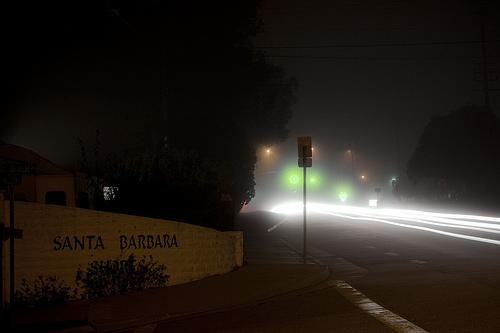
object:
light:
[281, 199, 498, 245]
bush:
[68, 249, 177, 306]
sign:
[0, 186, 251, 314]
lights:
[276, 156, 334, 194]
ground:
[284, 199, 500, 258]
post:
[288, 129, 317, 247]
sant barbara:
[46, 230, 189, 255]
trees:
[70, 21, 298, 223]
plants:
[61, 256, 176, 333]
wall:
[0, 196, 245, 321]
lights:
[321, 176, 356, 207]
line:
[336, 281, 427, 332]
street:
[270, 193, 500, 333]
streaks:
[268, 199, 495, 236]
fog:
[256, 135, 430, 234]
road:
[272, 194, 493, 333]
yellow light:
[261, 142, 280, 163]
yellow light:
[310, 140, 321, 155]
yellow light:
[356, 170, 368, 185]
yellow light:
[339, 143, 355, 158]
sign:
[283, 127, 320, 269]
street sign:
[296, 134, 314, 261]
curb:
[1, 202, 425, 332]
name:
[48, 228, 182, 256]